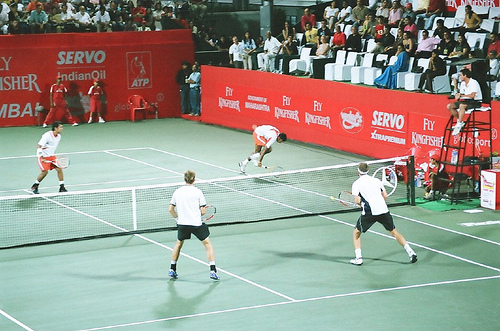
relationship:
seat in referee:
[429, 59, 486, 196] [439, 67, 481, 139]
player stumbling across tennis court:
[238, 122, 286, 174] [3, 123, 498, 329]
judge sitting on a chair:
[446, 67, 481, 134] [433, 56, 493, 206]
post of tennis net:
[404, 152, 429, 208] [2, 142, 412, 248]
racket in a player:
[251, 159, 286, 176] [238, 122, 286, 174]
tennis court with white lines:
[3, 123, 498, 329] [1, 144, 499, 329]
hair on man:
[278, 128, 290, 141] [238, 121, 287, 167]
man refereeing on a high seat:
[350, 160, 419, 264] [422, 93, 483, 194]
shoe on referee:
[450, 119, 464, 136] [439, 67, 481, 139]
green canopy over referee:
[449, 57, 481, 64] [446, 67, 483, 135]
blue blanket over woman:
[373, 54, 413, 86] [363, 39, 408, 96]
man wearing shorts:
[166, 169, 245, 297] [169, 222, 213, 246]